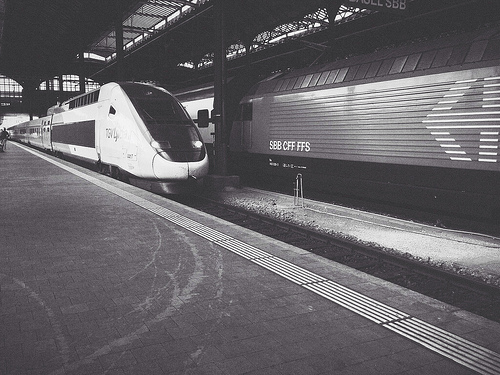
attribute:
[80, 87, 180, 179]
train — white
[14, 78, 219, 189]
train — white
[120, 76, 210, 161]
train hood — black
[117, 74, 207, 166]
hood — black, train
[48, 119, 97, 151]
window — black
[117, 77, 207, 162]
window — black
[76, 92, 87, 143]
window — black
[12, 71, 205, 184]
train — passenger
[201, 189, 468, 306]
track — railroad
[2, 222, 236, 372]
stains — white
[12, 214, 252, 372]
stains — white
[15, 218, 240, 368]
stains — white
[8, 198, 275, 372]
stains — white